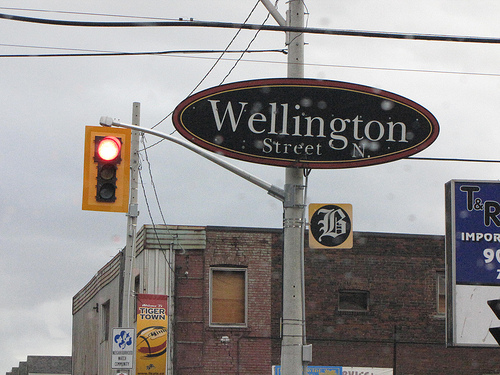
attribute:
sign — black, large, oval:
[176, 76, 446, 169]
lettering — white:
[209, 94, 416, 156]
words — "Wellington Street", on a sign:
[201, 95, 411, 155]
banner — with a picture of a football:
[132, 290, 171, 373]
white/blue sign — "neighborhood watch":
[109, 324, 138, 370]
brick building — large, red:
[181, 229, 435, 361]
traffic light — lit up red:
[87, 129, 128, 208]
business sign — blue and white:
[445, 168, 485, 352]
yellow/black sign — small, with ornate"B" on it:
[306, 200, 356, 250]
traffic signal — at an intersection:
[79, 117, 135, 217]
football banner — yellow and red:
[131, 288, 172, 371]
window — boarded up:
[207, 264, 249, 330]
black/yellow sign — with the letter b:
[306, 198, 355, 252]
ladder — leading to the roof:
[168, 246, 210, 372]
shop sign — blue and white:
[440, 174, 483, 348]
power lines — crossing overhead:
[2, 2, 484, 80]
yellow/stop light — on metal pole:
[79, 122, 138, 214]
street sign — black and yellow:
[305, 199, 356, 251]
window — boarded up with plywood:
[206, 265, 251, 328]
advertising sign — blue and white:
[439, 174, 484, 350]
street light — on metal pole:
[96, 111, 323, 372]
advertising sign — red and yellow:
[133, 289, 173, 372]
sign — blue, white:
[108, 324, 138, 372]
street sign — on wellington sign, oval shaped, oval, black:
[168, 74, 446, 170]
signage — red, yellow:
[135, 290, 169, 372]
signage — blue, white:
[441, 174, 484, 348]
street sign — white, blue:
[109, 327, 136, 373]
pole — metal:
[281, 3, 308, 373]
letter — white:
[312, 204, 349, 247]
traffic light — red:
[92, 133, 121, 163]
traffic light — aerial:
[77, 121, 137, 217]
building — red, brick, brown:
[64, 219, 484, 373]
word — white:
[202, 92, 412, 152]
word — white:
[260, 136, 328, 161]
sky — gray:
[1, 2, 484, 333]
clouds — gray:
[2, 73, 282, 296]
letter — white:
[206, 95, 246, 135]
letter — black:
[455, 182, 481, 214]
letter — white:
[324, 114, 350, 155]